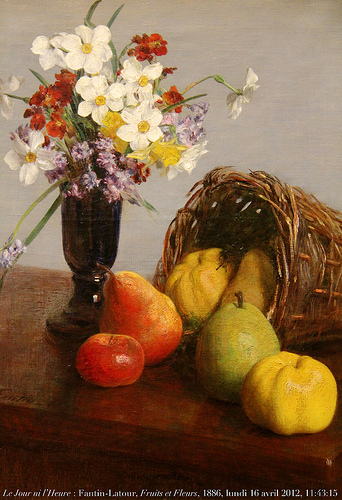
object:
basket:
[152, 166, 342, 352]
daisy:
[0, 25, 260, 186]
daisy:
[120, 57, 163, 105]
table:
[0, 263, 342, 500]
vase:
[45, 196, 122, 339]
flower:
[119, 100, 166, 150]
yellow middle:
[137, 120, 150, 133]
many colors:
[0, 24, 210, 225]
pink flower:
[160, 113, 178, 124]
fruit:
[75, 247, 337, 435]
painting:
[0, 0, 342, 500]